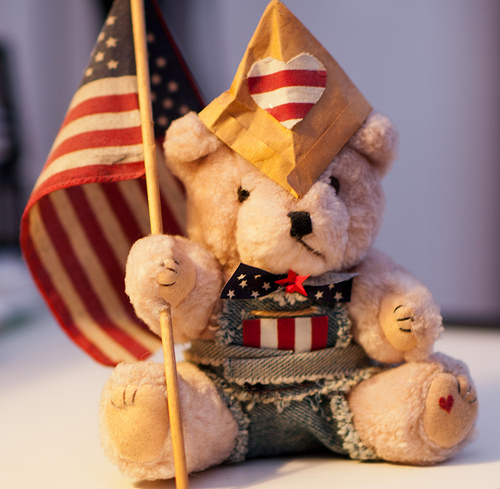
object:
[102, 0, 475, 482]
teddy bear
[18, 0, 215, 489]
flag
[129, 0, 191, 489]
stick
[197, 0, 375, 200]
hat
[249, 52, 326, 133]
striped heart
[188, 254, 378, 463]
overalls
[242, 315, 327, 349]
stripe design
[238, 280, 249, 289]
stars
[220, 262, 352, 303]
bowtie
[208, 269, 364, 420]
front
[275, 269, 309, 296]
star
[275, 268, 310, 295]
sequin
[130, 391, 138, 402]
stitching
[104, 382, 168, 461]
paw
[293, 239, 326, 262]
stitching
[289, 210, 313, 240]
nose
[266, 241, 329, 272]
mouth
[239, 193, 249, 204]
stitching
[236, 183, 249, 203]
eye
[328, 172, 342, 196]
eye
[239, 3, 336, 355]
colors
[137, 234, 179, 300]
hand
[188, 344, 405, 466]
shorts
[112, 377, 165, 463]
front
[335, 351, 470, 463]
leg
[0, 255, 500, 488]
table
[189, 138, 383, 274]
face